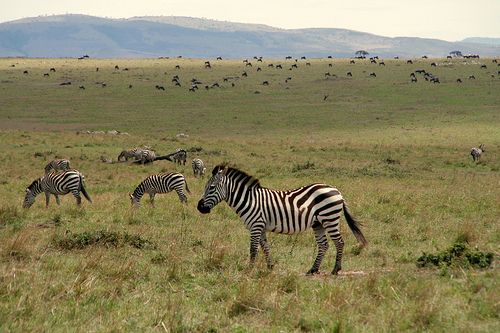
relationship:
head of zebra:
[188, 152, 246, 226] [196, 163, 366, 276]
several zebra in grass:
[17, 139, 368, 286] [281, 103, 464, 172]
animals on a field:
[41, 131, 386, 283] [0, 51, 499, 332]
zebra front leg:
[196, 163, 366, 276] [249, 220, 261, 272]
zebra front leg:
[196, 163, 366, 276] [259, 231, 271, 263]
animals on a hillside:
[153, 51, 311, 104] [268, 28, 373, 149]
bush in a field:
[403, 228, 497, 290] [252, 56, 419, 166]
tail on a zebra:
[339, 188, 366, 246] [201, 147, 377, 281]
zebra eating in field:
[188, 134, 375, 275] [310, 83, 428, 206]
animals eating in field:
[19, 169, 93, 212] [350, 110, 473, 217]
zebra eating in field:
[196, 163, 366, 276] [0, 56, 499, 331]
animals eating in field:
[19, 169, 93, 212] [0, 56, 499, 331]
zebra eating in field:
[41, 158, 73, 173] [0, 56, 499, 331]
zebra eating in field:
[127, 171, 192, 206] [0, 56, 499, 331]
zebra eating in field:
[469, 141, 486, 163] [0, 56, 499, 331]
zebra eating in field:
[190, 158, 205, 177] [217, 81, 377, 157]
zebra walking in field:
[131, 172, 190, 206] [29, 59, 487, 312]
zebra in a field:
[196, 163, 366, 276] [221, 97, 355, 157]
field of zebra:
[0, 56, 499, 331] [196, 163, 366, 276]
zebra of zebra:
[196, 163, 366, 276] [127, 171, 192, 206]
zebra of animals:
[196, 163, 366, 276] [19, 169, 93, 212]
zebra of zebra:
[196, 163, 366, 276] [44, 156, 71, 174]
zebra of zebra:
[196, 163, 366, 276] [189, 156, 206, 177]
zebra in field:
[41, 158, 73, 173] [0, 56, 499, 331]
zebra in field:
[190, 158, 205, 177] [0, 56, 499, 331]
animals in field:
[19, 169, 93, 212] [0, 56, 499, 331]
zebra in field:
[127, 171, 192, 206] [0, 56, 499, 331]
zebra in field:
[196, 163, 366, 276] [0, 56, 499, 331]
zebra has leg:
[196, 163, 366, 276] [246, 220, 266, 263]